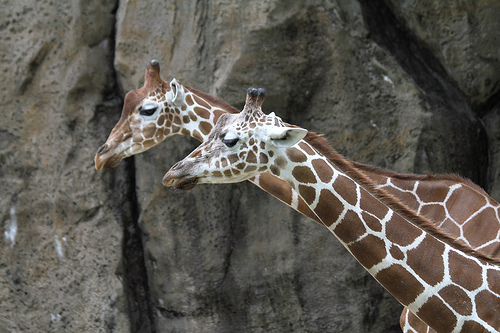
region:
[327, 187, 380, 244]
White and brown patches.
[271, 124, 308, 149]
White ears in the photo.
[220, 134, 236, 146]
Black eyes in the photo.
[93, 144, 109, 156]
Black nose in the photo.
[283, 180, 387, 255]
A long giraffe neck.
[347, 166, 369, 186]
Brown fur in the picture.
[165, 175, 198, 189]
A brown mouth in the photo.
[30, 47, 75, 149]
Big stone wall in the photo.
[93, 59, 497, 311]
Two giraffes in the photo.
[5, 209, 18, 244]
White mark on the wall.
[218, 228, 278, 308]
par of a rock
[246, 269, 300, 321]
part of a stone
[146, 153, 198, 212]
part of a mouth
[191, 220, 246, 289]
part of a stone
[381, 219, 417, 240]
spot on the giraffe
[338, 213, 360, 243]
spot on the giraffe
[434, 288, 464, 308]
spot on the giraffe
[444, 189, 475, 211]
spot on the giraffe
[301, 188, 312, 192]
spot on the giraffe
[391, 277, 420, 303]
spot on the giraffe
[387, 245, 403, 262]
spot on the giraffe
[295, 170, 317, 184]
spot on the giraffe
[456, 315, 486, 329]
spot on the giraffe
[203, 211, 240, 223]
part of a rock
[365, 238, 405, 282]
neck of a giraffe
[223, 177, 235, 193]
mouth of a giraffe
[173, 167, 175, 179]
tip of a mouth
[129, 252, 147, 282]
side of a rock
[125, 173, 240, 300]
part of a mountain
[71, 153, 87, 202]
edge of mountain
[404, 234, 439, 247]
back of a giraffe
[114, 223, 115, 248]
side of a rock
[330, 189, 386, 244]
Brown and white skin patches.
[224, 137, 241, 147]
Black eye in the photo.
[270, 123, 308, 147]
White ear in the photo.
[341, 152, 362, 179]
Brown fur in the photo.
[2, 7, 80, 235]
A stone wall in the photo.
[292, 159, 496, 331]
Long giraffe necks in the photo.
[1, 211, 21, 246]
White marks on the wall.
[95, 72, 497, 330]
Two giraffes in the picture.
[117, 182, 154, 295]
Cracks on the wall.